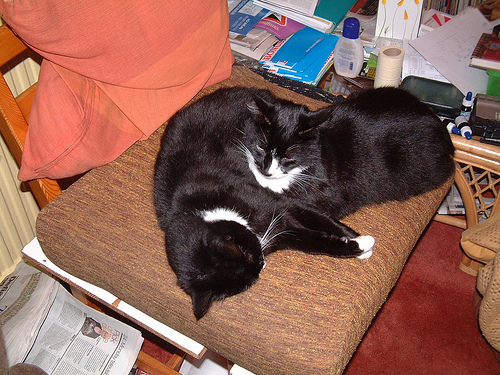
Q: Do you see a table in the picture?
A: Yes, there is a table.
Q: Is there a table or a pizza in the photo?
A: Yes, there is a table.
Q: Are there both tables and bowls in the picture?
A: No, there is a table but no bowls.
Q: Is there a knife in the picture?
A: No, there are no knives.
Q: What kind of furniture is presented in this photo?
A: The furniture is a table.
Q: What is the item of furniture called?
A: The piece of furniture is a table.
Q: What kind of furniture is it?
A: The piece of furniture is a table.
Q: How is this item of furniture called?
A: This is a table.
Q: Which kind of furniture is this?
A: This is a table.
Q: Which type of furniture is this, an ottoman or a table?
A: This is a table.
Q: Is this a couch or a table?
A: This is a table.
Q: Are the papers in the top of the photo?
A: Yes, the papers are in the top of the image.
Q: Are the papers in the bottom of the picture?
A: No, the papers are in the top of the image.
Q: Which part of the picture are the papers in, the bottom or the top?
A: The papers are in the top of the image.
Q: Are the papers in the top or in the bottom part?
A: The papers are in the top of the image.